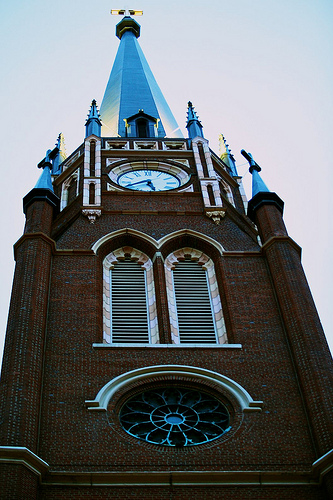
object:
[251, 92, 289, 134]
ground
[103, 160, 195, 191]
clock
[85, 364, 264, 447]
window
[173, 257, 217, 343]
slats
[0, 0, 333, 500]
picture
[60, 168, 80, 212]
window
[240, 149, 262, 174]
cross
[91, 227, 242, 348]
window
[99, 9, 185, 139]
steeple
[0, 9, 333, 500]
building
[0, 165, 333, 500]
column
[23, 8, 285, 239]
roof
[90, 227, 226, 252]
dormer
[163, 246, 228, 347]
tile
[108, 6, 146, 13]
top